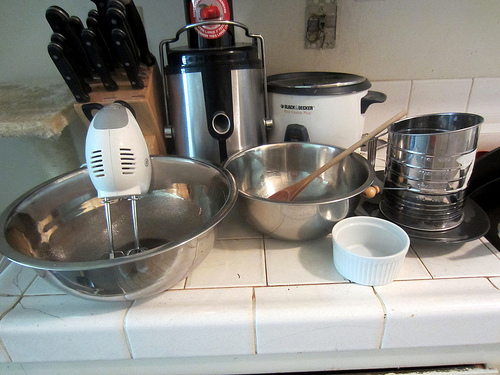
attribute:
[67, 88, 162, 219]
mixer — white and gray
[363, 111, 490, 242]
sifter — silver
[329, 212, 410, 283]
ramekin — white, small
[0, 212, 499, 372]
counter — tiled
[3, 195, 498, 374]
counter top — white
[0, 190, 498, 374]
counter — tiled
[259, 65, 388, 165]
crock pot — white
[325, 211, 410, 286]
bowl — white, porcelain, souffle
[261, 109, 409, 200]
spoon — long, wooden, mixing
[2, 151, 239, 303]
bowl — mixing, dirty, stainless steel, silver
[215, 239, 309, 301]
grout — dirty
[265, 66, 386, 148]
crock pot — small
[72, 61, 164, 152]
brick — wood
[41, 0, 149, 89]
knives — a bunch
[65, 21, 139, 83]
handles — black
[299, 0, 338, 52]
outlet — broken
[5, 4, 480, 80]
wall — concrete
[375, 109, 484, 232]
sifter — flour, old fashioned, silver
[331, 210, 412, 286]
bowl — white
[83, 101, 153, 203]
mixer — white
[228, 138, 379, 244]
bowl — silver, round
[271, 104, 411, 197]
spoon — wooden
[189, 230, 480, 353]
counter — kitchen, white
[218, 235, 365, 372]
counter — white, kitchen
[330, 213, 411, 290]
bowl — round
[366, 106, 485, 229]
sifter — flour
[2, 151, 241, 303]
mixing bowl — silver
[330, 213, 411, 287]
container — white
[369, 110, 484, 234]
measuring cup — silver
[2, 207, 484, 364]
countertop — white, tiled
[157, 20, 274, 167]
container — silver, black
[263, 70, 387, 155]
crock pot — white, Black & Decker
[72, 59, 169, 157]
block — wooden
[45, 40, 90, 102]
knife — black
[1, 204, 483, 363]
counter — white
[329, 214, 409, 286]
dish — white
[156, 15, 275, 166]
appliance — silver